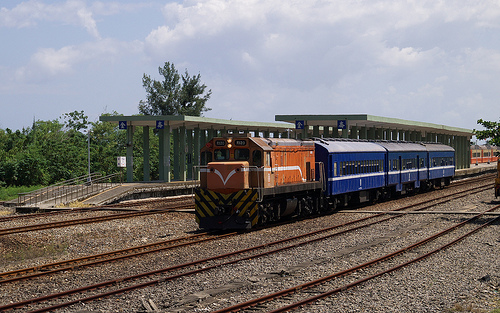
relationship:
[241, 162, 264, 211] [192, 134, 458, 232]
railing on front of passenger car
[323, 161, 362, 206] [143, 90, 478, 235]
window on front of train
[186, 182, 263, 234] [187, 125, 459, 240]
stripes on front of train engine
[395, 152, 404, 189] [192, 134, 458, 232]
door on passenger car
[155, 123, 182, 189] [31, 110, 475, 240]
support post on train platform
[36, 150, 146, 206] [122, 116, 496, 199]
ramp going up to train platform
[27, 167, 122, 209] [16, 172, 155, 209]
railing on ramp